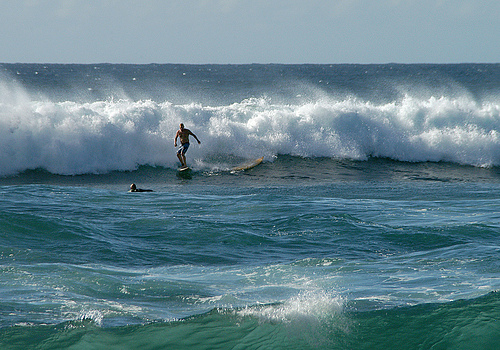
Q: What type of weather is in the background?
A: It is clear.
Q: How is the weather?
A: It is clear.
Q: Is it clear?
A: Yes, it is clear.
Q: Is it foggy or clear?
A: It is clear.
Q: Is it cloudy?
A: No, it is clear.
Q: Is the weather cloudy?
A: No, it is clear.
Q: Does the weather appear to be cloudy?
A: No, it is clear.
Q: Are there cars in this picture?
A: No, there are no cars.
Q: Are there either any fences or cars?
A: No, there are no cars or fences.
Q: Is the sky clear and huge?
A: Yes, the sky is clear and huge.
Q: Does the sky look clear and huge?
A: Yes, the sky is clear and huge.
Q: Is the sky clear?
A: Yes, the sky is clear.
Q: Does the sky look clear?
A: Yes, the sky is clear.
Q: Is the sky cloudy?
A: No, the sky is clear.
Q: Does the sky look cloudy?
A: No, the sky is clear.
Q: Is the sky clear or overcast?
A: The sky is clear.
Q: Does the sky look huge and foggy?
A: No, the sky is huge but clear.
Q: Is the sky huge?
A: Yes, the sky is huge.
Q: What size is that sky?
A: The sky is huge.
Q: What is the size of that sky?
A: The sky is huge.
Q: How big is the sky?
A: The sky is huge.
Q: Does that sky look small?
A: No, the sky is huge.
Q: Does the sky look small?
A: No, the sky is huge.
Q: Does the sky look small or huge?
A: The sky is huge.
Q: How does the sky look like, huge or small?
A: The sky is huge.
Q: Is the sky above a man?
A: Yes, the sky is above a man.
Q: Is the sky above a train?
A: No, the sky is above a man.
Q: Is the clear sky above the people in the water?
A: Yes, the sky is above the people.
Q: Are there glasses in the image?
A: No, there are no glasses.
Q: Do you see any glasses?
A: No, there are no glasses.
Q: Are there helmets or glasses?
A: No, there are no glasses or helmets.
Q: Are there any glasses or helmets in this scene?
A: No, there are no glasses or helmets.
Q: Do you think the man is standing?
A: Yes, the man is standing.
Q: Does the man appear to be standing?
A: Yes, the man is standing.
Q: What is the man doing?
A: The man is standing.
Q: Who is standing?
A: The man is standing.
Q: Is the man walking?
A: No, the man is standing.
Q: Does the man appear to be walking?
A: No, the man is standing.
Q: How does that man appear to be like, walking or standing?
A: The man is standing.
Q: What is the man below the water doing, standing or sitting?
A: The man is standing.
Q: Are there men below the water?
A: Yes, there is a man below the water.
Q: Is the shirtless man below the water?
A: Yes, the man is below the water.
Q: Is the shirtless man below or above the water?
A: The man is below the water.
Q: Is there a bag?
A: No, there are no bags.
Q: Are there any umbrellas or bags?
A: No, there are no bags or umbrellas.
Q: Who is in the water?
A: The people are in the water.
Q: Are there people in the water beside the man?
A: Yes, there are people in the water.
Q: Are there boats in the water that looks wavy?
A: No, there are people in the water.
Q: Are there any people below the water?
A: Yes, there are people below the water.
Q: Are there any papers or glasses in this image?
A: No, there are no glasses or papers.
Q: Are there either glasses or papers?
A: No, there are no glasses or papers.